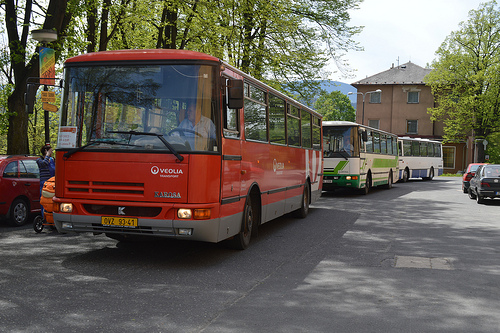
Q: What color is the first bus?
A: Orange.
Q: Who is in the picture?
A: A bus driver.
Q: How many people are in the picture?
A: One.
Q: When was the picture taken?
A: During the day.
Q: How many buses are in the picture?
A: Three.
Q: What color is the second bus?
A: White and green.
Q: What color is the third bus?
A: Blue and white.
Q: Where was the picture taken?
A: On the street.